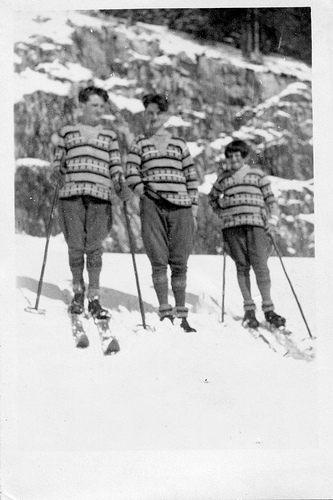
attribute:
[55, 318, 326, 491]
snow — covering, present, here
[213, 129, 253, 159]
hair — short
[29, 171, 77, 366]
pole — held, metal, long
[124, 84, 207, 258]
man — standing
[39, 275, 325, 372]
skies — worn, dark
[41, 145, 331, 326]
kids — wearing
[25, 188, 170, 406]
poles — held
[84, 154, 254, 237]
hands — holding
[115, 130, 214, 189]
sweater — patterned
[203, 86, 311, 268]
girl — standing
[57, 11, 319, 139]
slope — snowy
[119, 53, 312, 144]
cliff — rocky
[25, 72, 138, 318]
skis — standing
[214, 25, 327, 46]
tree — covered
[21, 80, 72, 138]
rock — covered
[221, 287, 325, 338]
boots — black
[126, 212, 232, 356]
pants — baggy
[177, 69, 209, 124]
stone — filled